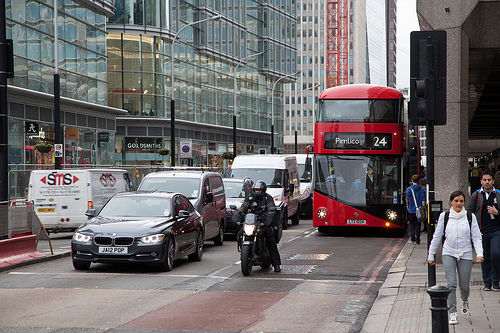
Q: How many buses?
A: 1.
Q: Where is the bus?
A: On the street.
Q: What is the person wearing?
A: Helmet.